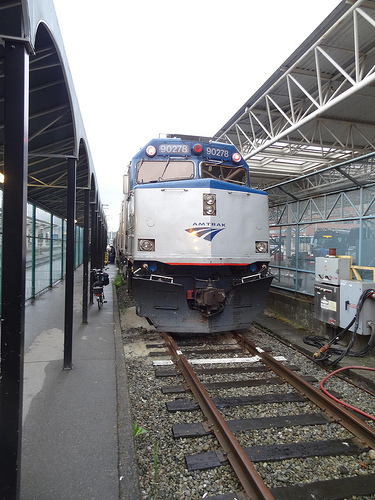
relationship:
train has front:
[112, 133, 274, 336] [129, 134, 276, 334]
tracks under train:
[139, 325, 375, 498] [112, 133, 274, 336]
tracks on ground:
[139, 325, 375, 498] [20, 247, 374, 498]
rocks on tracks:
[120, 285, 373, 499] [139, 325, 375, 498]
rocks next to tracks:
[120, 285, 373, 499] [139, 325, 375, 498]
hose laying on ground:
[320, 364, 373, 422] [20, 247, 374, 498]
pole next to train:
[64, 158, 78, 369] [112, 133, 274, 336]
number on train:
[159, 143, 228, 158] [112, 133, 274, 336]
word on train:
[191, 221, 228, 228] [112, 133, 274, 336]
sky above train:
[53, 0, 343, 232] [112, 133, 274, 336]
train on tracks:
[112, 133, 274, 336] [139, 325, 375, 498]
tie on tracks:
[183, 434, 374, 472] [139, 325, 375, 498]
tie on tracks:
[171, 410, 373, 439] [139, 325, 375, 498]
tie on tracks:
[201, 474, 374, 499] [139, 325, 375, 498]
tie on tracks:
[166, 388, 345, 414] [139, 325, 375, 498]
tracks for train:
[139, 325, 375, 498] [112, 133, 274, 336]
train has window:
[112, 133, 274, 336] [135, 159, 197, 184]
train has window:
[112, 133, 274, 336] [198, 160, 249, 186]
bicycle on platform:
[90, 267, 108, 311] [21, 262, 138, 499]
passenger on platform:
[109, 245, 118, 263] [21, 262, 138, 499]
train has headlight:
[112, 133, 274, 336] [204, 195, 216, 216]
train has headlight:
[112, 133, 274, 336] [138, 239, 154, 253]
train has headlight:
[112, 133, 274, 336] [255, 240, 269, 252]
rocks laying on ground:
[120, 285, 373, 499] [20, 247, 374, 498]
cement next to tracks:
[21, 262, 138, 499] [139, 325, 375, 498]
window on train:
[135, 159, 197, 184] [112, 133, 274, 336]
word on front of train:
[191, 221, 228, 228] [112, 133, 274, 336]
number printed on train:
[159, 143, 228, 158] [112, 133, 274, 336]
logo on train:
[183, 221, 228, 243] [112, 133, 274, 336]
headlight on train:
[204, 195, 216, 216] [112, 133, 274, 336]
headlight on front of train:
[204, 195, 216, 216] [112, 133, 274, 336]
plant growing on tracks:
[132, 419, 148, 437] [139, 325, 375, 498]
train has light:
[112, 133, 274, 336] [192, 143, 204, 153]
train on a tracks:
[112, 133, 274, 336] [139, 325, 375, 498]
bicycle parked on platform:
[90, 267, 108, 311] [21, 262, 138, 499]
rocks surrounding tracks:
[120, 285, 373, 499] [139, 325, 375, 498]